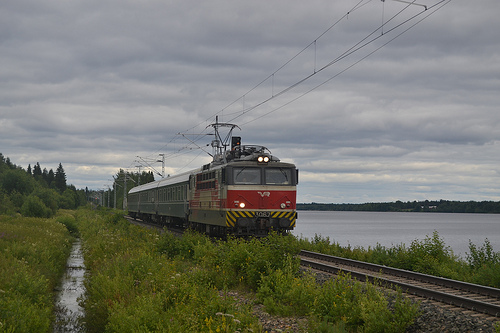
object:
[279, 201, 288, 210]
headlights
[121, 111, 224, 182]
cables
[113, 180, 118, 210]
pole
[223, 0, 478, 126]
cables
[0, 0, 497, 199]
sky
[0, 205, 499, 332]
weeds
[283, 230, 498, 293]
weeds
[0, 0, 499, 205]
clouds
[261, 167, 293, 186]
window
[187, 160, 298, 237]
train car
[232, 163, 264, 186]
windshield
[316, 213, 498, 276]
lake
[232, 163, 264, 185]
window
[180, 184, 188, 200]
window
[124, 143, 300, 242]
train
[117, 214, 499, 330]
railroad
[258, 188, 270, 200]
number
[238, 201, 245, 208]
headlight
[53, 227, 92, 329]
creek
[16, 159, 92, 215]
trees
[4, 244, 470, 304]
ground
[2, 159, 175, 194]
distance